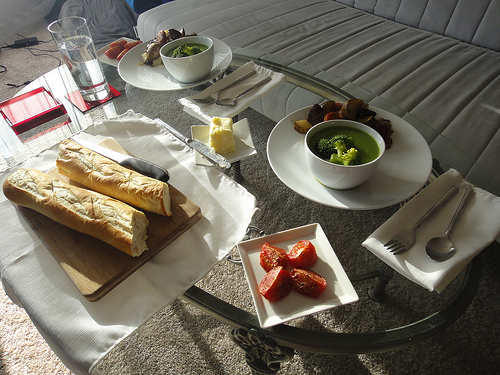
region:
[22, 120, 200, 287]
two pieces of french bread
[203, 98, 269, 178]
part of a butter stick on the table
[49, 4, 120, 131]
glass of water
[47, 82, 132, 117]
glass is on a coaster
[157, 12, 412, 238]
two plates on the table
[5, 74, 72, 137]
coaster holder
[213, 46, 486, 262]
two sets of spoon and fork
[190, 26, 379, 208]
two bowls of brocolli soup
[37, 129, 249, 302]
bread on a cutting board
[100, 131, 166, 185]
knife is on the cutting board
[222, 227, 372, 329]
a plate of tomatoes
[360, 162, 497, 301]
silverware on a white napkin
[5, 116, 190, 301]
loaves of bread on a cutting board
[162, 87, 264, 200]
a plate of butter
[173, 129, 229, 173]
a used butterknife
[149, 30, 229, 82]
white bowl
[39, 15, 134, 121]
clear cup of water on the table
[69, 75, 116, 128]
red coaster under the cup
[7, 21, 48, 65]
black computer cord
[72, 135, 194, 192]
black knife for bread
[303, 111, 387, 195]
soup in a bowl with broccoli on top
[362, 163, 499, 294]
silver fork and spoon on a white napkin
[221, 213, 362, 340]
grilled tomatoes on a white square plate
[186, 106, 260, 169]
a chick of yellow butter on a small dish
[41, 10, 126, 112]
a glass of water on a red coaster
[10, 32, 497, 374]
the table is glass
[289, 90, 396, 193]
a pile of vegetables beside the bowl of soup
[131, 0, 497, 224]
the seat is white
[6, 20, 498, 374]
the carpet is light brown colored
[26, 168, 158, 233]
loafs of bread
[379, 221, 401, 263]
a fork on the napkin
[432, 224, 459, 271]
a silver spoon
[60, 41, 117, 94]
a glass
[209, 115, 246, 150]
the butter is yellow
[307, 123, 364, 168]
the brocolli is green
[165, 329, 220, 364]
carpet on the floor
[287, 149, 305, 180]
a white plate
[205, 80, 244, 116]
silverware on the napkin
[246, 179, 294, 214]
a glass table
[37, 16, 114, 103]
A tall glass of water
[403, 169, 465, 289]
a shoddy place setting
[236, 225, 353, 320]
A plate of tomato quarters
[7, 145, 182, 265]
Bread and knife on a cutting board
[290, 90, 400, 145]
Oven roasted seasoned vegetables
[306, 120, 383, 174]
Pea and broccoli soup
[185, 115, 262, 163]
A one inch long piece of butter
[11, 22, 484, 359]
A glass table set for a meal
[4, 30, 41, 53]
A laptop power adapter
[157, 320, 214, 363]
Light colored carpet